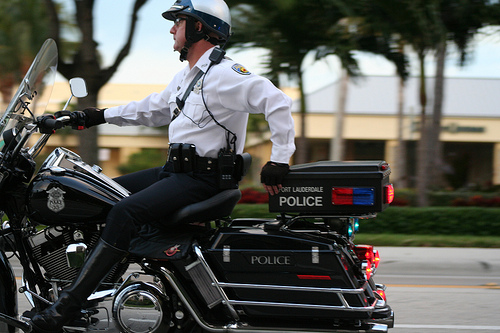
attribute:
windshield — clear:
[0, 36, 59, 158]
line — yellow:
[380, 276, 497, 292]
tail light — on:
[383, 180, 395, 206]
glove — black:
[257, 156, 292, 189]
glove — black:
[51, 104, 113, 128]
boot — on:
[29, 235, 130, 331]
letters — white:
[278, 185, 323, 207]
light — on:
[355, 244, 379, 277]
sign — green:
[408, 118, 488, 136]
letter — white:
[277, 195, 287, 207]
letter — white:
[285, 193, 295, 205]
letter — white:
[294, 193, 304, 208]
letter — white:
[304, 191, 316, 206]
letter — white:
[312, 193, 324, 206]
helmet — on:
[160, 0, 232, 62]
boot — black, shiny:
[24, 242, 122, 327]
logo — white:
[44, 187, 65, 212]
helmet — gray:
[162, 1, 231, 40]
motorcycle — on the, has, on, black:
[1, 37, 396, 331]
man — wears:
[26, 3, 296, 331]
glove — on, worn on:
[266, 166, 284, 184]